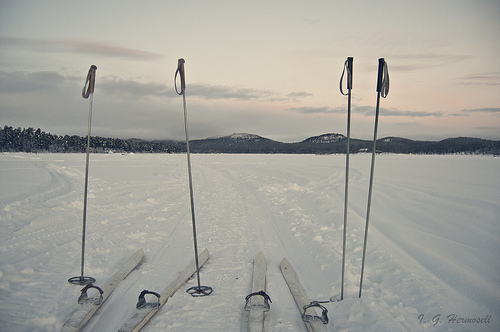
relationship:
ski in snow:
[51, 243, 150, 331] [51, 186, 430, 331]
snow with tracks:
[51, 186, 430, 331] [310, 183, 416, 331]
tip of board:
[120, 247, 151, 267] [51, 243, 150, 331]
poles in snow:
[335, 53, 392, 304] [51, 186, 430, 331]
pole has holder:
[165, 52, 223, 301] [172, 57, 193, 101]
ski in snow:
[117, 241, 213, 331] [51, 186, 430, 331]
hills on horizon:
[420, 135, 498, 156] [302, 124, 499, 158]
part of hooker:
[335, 77, 356, 99] [338, 49, 357, 105]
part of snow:
[118, 161, 178, 217] [51, 186, 430, 331]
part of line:
[14, 192, 77, 239] [0, 152, 80, 269]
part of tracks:
[327, 256, 419, 314] [310, 183, 416, 331]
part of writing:
[417, 314, 454, 330] [414, 311, 497, 328]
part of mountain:
[205, 127, 282, 154] [207, 130, 345, 157]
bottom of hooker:
[183, 282, 219, 301] [169, 56, 194, 104]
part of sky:
[213, 74, 341, 123] [137, 58, 414, 124]